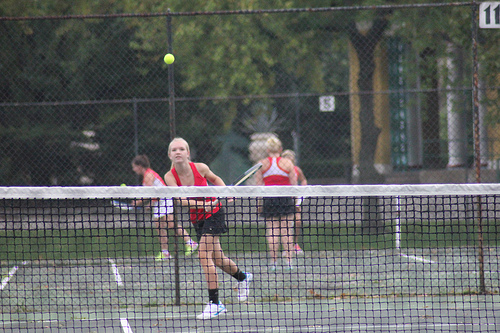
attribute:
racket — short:
[202, 157, 267, 216]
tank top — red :
[260, 155, 294, 195]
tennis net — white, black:
[5, 190, 499, 327]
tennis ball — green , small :
[157, 48, 183, 68]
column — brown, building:
[332, 29, 409, 203]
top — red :
[171, 160, 223, 217]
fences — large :
[1, 3, 498, 311]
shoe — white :
[174, 297, 239, 322]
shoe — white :
[232, 265, 260, 297]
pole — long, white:
[106, 254, 125, 286]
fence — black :
[9, 15, 497, 237]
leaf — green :
[266, 57, 276, 65]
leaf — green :
[238, 54, 248, 66]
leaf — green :
[190, 23, 197, 32]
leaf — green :
[130, 43, 143, 53]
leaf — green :
[145, 5, 155, 17]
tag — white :
[317, 93, 337, 112]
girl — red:
[162, 137, 254, 319]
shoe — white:
[196, 303, 226, 319]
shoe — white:
[236, 272, 252, 298]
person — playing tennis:
[158, 137, 257, 322]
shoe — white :
[235, 272, 253, 304]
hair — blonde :
[264, 137, 282, 156]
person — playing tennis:
[111, 151, 199, 262]